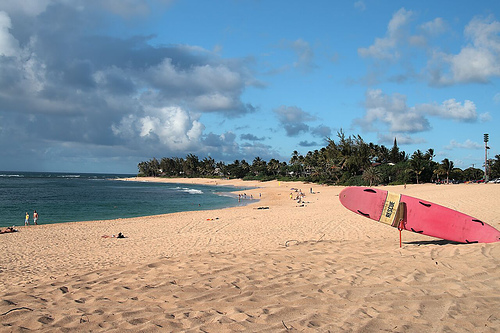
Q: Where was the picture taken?
A: It was taken at the beach.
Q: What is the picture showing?
A: It is showing a beach.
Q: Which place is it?
A: It is a beach.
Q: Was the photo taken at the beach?
A: Yes, it was taken in the beach.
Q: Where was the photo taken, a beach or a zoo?
A: It was taken at a beach.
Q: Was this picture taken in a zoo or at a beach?
A: It was taken at a beach.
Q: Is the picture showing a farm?
A: No, the picture is showing a beach.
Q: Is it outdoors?
A: Yes, it is outdoors.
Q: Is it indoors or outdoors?
A: It is outdoors.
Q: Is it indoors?
A: No, it is outdoors.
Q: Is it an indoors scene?
A: No, it is outdoors.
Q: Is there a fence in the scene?
A: No, there are no fences.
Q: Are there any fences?
A: No, there are no fences.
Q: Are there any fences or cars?
A: No, there are no fences or cars.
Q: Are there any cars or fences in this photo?
A: No, there are no fences or cars.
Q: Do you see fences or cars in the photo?
A: No, there are no fences or cars.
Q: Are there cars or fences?
A: No, there are no fences or cars.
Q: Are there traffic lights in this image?
A: No, there are no traffic lights.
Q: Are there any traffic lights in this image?
A: No, there are no traffic lights.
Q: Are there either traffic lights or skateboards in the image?
A: No, there are no traffic lights or skateboards.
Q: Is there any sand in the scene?
A: Yes, there is sand.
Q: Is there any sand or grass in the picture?
A: Yes, there is sand.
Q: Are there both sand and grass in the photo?
A: No, there is sand but no grass.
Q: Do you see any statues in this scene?
A: No, there are no statues.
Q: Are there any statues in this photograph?
A: No, there are no statues.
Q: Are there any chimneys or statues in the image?
A: No, there are no statues or chimneys.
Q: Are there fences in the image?
A: No, there are no fences.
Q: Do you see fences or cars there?
A: No, there are no fences or cars.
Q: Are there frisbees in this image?
A: No, there are no frisbees.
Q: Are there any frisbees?
A: No, there are no frisbees.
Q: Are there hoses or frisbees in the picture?
A: No, there are no frisbees or hoses.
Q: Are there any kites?
A: No, there are no kites.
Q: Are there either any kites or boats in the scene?
A: No, there are no kites or boats.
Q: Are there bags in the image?
A: No, there are no bags.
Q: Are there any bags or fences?
A: No, there are no bags or fences.